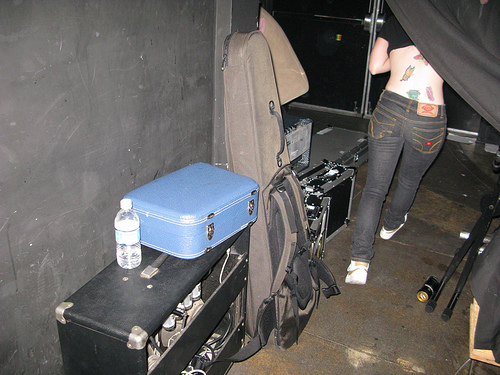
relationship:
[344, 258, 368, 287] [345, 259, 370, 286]
shoe on foot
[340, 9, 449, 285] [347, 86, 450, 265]
person wearing pants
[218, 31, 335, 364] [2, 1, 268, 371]
guitar case is leaning against wall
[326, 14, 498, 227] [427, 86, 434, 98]
person has tattoo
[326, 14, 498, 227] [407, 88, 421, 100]
person has tattoo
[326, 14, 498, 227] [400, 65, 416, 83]
person has tattoo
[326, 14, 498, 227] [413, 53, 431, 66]
person has tattoo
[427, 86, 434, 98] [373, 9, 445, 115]
tattoo on back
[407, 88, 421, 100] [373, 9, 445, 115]
tattoo on back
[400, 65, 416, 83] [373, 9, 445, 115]
tattoo on back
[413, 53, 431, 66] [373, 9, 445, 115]
tattoo on back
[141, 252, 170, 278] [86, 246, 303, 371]
handle on amp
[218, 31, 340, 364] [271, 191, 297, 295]
guitar case has shoulder strap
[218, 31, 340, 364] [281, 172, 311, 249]
guitar case has shoulder strap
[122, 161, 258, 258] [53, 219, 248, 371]
blue luggage on black case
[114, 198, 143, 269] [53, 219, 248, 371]
bottle on black case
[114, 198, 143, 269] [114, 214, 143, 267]
bottle of water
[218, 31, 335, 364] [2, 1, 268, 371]
guitar case on wall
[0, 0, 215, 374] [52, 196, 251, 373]
wall beside case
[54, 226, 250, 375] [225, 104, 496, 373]
black case on floor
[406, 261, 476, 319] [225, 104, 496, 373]
can on floor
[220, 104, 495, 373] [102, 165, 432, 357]
floor below suitcase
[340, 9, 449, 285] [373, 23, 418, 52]
person wearing a shirt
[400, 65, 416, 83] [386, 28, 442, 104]
tattoo on back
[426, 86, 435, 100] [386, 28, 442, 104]
tattoo on back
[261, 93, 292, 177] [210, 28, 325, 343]
handle on case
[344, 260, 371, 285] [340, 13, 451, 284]
shoe of person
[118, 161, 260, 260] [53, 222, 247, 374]
blue luggage on stand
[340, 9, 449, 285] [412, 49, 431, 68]
person has tattoo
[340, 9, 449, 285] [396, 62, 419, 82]
person has tattoo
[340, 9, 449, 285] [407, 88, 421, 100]
person has tattoo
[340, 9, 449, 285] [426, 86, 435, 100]
person has tattoo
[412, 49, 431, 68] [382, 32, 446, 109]
tattoo on back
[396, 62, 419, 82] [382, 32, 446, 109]
tattoo on back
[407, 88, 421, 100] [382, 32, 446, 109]
tattoo on back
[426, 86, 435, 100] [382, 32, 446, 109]
tattoo on back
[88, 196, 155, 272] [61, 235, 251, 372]
bottle on stand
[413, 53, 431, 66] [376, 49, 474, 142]
tattoo on back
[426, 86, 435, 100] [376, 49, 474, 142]
tattoo on back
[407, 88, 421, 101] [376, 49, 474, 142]
tattoo on back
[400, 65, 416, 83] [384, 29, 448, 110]
tattoo on back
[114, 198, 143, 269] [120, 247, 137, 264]
bottle of water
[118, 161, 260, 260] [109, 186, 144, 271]
blue luggage by bottle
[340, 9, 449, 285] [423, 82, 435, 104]
person has tattoo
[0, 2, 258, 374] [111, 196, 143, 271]
wall behind bottle